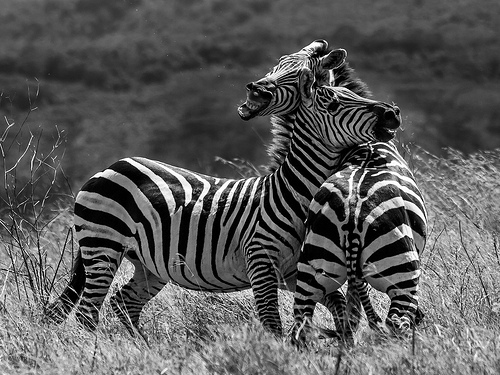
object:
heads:
[237, 40, 348, 122]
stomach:
[139, 255, 248, 294]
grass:
[0, 81, 64, 308]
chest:
[276, 212, 308, 281]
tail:
[345, 237, 363, 331]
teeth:
[252, 106, 256, 110]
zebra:
[237, 39, 428, 352]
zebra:
[38, 67, 400, 344]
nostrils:
[373, 106, 385, 115]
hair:
[334, 62, 374, 101]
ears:
[320, 48, 348, 70]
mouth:
[236, 82, 273, 121]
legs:
[75, 239, 127, 333]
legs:
[109, 267, 169, 344]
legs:
[243, 242, 283, 339]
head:
[288, 67, 401, 151]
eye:
[327, 99, 340, 112]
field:
[0, 216, 500, 375]